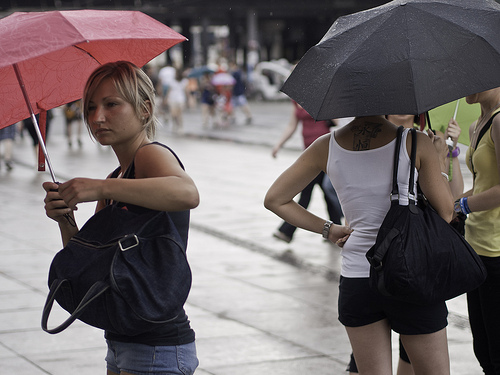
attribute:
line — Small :
[244, 293, 328, 374]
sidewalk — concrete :
[2, 63, 495, 373]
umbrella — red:
[0, 8, 192, 230]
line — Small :
[270, 285, 325, 315]